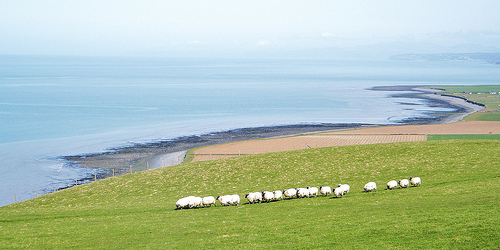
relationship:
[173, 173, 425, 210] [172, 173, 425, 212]
sheep in line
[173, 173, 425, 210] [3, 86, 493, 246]
sheep in grass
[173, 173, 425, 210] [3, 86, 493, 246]
sheep grazing in grass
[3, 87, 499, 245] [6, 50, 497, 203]
field beside ocean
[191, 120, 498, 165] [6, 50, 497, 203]
shore against ocean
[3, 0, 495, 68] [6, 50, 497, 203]
sky fades into ocean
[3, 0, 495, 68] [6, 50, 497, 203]
sky into ocean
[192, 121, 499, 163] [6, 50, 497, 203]
strip between ocean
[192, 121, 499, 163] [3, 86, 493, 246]
strip between grass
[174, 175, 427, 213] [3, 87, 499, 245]
animals in field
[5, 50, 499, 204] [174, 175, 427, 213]
water next to animals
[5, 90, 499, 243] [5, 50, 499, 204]
land next to water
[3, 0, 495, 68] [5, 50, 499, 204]
sky above water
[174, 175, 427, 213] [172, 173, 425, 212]
animals in row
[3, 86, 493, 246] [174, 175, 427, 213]
grass next to animals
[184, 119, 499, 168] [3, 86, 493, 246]
land next to grass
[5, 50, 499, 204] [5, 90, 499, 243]
water next to land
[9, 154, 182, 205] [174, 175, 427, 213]
fence next to animals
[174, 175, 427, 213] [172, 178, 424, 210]
animals in group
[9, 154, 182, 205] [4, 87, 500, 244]
fence on landscape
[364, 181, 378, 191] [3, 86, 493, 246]
sheep eating grass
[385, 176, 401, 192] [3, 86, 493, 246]
sheep eating grass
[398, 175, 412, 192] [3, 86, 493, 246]
sheep eating grass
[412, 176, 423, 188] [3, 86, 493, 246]
sheep eating grass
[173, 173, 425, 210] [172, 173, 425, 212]
sheep walking in line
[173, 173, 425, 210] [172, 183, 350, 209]
sheep in group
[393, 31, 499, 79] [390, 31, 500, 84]
mountains covered in clouds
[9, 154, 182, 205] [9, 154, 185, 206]
fence with poles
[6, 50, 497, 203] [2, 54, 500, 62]
ocean has horizon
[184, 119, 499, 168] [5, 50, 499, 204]
land touching water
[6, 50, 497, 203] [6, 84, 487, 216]
ocean has shore line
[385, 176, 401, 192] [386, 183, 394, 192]
sheep with head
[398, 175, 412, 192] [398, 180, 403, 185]
sheep with head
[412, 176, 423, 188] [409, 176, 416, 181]
sheep with head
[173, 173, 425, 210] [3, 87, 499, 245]
sheep in field